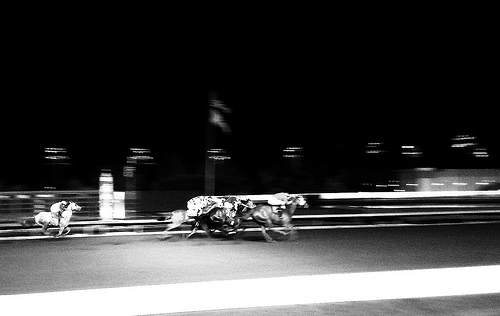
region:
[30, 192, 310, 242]
Horses are in a race.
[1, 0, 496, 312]
The image is in black and white.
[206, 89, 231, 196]
Tow flags are flying on a pole.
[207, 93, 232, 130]
Wind is making two flagsflutter.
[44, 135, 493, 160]
Blurry lights are shining.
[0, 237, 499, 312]
Light is shining on the ground.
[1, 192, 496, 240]
The horses are running by a fence.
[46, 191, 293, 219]
The riders are bent over.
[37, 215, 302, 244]
The horse legs are in a running position.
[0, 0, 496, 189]
Artificial light is shining from lights at night.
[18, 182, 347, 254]
horses racing down track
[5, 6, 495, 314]
black and white photo of horses racing down track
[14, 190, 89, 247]
white horse racing down track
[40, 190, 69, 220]
jockey on top of horse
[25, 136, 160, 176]
blurred lights lining horse track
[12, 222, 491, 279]
grey dirt track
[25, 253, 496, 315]
wide white line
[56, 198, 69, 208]
white hat on top of jockey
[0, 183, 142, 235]
fence on side of race track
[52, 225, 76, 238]
white legs of horse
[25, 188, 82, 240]
a man on a horse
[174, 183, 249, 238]
a man on a horse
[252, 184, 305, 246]
a man on a horse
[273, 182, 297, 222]
this is a man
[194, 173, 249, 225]
this is a man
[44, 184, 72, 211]
this is a man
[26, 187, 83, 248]
this is a horse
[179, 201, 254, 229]
this is a horse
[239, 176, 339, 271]
this is a horse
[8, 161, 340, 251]
this is a horse race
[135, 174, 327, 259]
horses racing on track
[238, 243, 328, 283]
dirt track under horses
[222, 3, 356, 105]
sky is black and dark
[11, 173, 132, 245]
horse behind other horses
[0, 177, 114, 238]
rail is behind horses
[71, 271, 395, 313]
white rail before track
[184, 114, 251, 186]
flags are behind horses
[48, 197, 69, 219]
jockey on horse in rear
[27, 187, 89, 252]
light colored horse in rear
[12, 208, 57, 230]
horse has long tail in rear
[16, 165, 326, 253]
a horse race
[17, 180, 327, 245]
horses running to the right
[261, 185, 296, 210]
horseman is crouched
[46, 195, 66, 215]
horseman is crouched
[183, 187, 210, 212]
the horseman is crouched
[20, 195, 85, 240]
the horse is in motion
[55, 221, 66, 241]
front legs of horse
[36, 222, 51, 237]
back legs of horse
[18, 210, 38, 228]
tail of horse is black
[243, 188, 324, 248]
horse running very fast